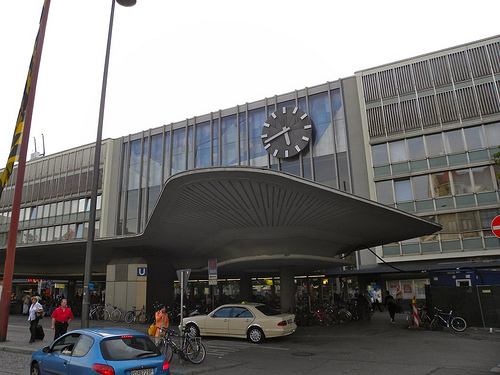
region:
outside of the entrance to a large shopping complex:
[12, 51, 489, 361]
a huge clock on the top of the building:
[251, 104, 318, 161]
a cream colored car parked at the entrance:
[179, 303, 303, 348]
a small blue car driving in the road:
[32, 329, 172, 374]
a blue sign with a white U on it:
[136, 262, 148, 281]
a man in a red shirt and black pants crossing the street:
[48, 294, 75, 339]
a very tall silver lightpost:
[76, 1, 121, 333]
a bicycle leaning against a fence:
[418, 306, 470, 336]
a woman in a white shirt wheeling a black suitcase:
[26, 294, 48, 342]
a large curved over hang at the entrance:
[150, 153, 448, 271]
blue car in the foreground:
[28, 328, 168, 373]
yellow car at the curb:
[180, 300, 295, 340]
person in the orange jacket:
[147, 305, 168, 343]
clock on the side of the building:
[262, 107, 314, 157]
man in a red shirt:
[50, 300, 73, 338]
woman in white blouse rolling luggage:
[26, 297, 44, 342]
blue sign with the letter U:
[139, 266, 146, 275]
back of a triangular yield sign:
[175, 270, 188, 332]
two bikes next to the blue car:
[156, 325, 207, 363]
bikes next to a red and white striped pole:
[405, 292, 467, 330]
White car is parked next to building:
[170, 289, 310, 348]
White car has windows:
[199, 297, 267, 327]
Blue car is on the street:
[28, 324, 192, 374]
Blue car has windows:
[43, 324, 95, 358]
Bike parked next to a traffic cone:
[408, 292, 476, 341]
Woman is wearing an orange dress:
[148, 301, 173, 343]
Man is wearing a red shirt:
[45, 302, 85, 326]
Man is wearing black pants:
[48, 313, 76, 349]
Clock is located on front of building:
[251, 100, 332, 170]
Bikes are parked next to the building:
[82, 286, 159, 326]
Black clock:
[259, 106, 316, 159]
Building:
[4, 33, 499, 373]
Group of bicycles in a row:
[91, 303, 151, 326]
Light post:
[79, 0, 141, 329]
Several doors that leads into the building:
[174, 276, 336, 304]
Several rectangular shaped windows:
[0, 192, 102, 248]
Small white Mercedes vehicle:
[179, 304, 299, 342]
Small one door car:
[28, 330, 172, 373]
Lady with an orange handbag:
[149, 306, 171, 344]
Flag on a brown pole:
[0, 1, 50, 341]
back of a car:
[281, 311, 293, 324]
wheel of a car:
[254, 330, 259, 335]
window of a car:
[232, 306, 244, 318]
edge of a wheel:
[191, 317, 199, 352]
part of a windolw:
[458, 211, 469, 265]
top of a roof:
[342, 193, 349, 200]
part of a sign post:
[490, 205, 497, 222]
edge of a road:
[382, 345, 396, 358]